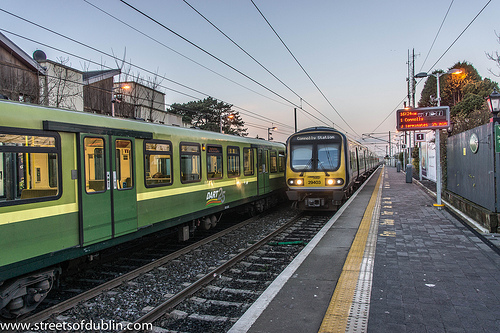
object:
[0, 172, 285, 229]
stripe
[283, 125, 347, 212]
front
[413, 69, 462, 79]
light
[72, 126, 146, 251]
doors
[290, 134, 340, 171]
windshield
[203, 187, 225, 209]
name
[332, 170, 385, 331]
stripe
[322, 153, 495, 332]
sidewalk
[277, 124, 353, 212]
engine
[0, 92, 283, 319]
car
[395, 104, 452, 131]
board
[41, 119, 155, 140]
lines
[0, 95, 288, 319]
train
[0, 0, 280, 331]
left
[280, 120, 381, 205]
right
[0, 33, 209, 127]
houses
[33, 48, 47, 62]
dish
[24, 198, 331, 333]
tracks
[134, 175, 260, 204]
line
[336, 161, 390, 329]
line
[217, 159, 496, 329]
platform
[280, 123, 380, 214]
train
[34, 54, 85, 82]
roof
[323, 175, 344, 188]
head light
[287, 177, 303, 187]
head light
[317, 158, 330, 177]
wiper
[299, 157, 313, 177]
wiper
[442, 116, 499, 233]
fence